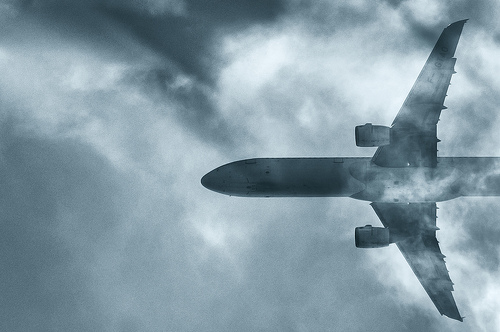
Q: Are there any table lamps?
A: No, there are no table lamps.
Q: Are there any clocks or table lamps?
A: No, there are no table lamps or clocks.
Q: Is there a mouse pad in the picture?
A: No, there are no mouse pads.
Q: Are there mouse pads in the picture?
A: No, there are no mouse pads.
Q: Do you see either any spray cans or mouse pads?
A: No, there are no mouse pads or spray cans.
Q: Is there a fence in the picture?
A: No, there are no fences.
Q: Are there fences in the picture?
A: No, there are no fences.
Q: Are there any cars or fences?
A: No, there are no fences or cars.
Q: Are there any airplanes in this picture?
A: Yes, there is an airplane.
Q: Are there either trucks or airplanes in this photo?
A: Yes, there is an airplane.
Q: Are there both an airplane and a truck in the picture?
A: No, there is an airplane but no trucks.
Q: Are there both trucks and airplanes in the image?
A: No, there is an airplane but no trucks.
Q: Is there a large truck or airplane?
A: Yes, there is a large airplane.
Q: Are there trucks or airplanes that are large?
A: Yes, the airplane is large.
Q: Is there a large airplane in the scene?
A: Yes, there is a large airplane.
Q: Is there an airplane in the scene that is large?
A: Yes, there is an airplane that is large.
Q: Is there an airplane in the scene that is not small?
A: Yes, there is a large airplane.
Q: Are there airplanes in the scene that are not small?
A: Yes, there is a large airplane.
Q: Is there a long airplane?
A: Yes, there is a long airplane.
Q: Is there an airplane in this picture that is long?
A: Yes, there is a long airplane.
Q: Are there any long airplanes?
A: Yes, there is a long airplane.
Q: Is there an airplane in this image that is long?
A: Yes, there is an airplane that is long.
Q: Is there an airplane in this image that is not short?
A: Yes, there is a long airplane.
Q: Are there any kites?
A: No, there are no kites.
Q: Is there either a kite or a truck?
A: No, there are no kites or trucks.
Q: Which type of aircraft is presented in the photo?
A: The aircraft is an airplane.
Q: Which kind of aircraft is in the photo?
A: The aircraft is an airplane.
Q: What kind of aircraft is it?
A: The aircraft is an airplane.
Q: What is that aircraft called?
A: This is an airplane.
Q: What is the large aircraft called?
A: The aircraft is an airplane.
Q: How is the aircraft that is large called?
A: The aircraft is an airplane.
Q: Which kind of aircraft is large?
A: The aircraft is an airplane.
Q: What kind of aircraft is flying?
A: The aircraft is an airplane.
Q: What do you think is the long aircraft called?
A: The aircraft is an airplane.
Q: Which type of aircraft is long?
A: The aircraft is an airplane.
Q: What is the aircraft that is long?
A: The aircraft is an airplane.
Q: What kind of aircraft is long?
A: The aircraft is an airplane.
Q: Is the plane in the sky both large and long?
A: Yes, the plane is large and long.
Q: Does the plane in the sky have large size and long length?
A: Yes, the plane is large and long.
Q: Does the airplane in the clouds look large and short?
A: No, the airplane is large but long.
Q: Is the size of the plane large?
A: Yes, the plane is large.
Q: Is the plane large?
A: Yes, the plane is large.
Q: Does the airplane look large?
A: Yes, the airplane is large.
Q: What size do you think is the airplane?
A: The airplane is large.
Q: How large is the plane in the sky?
A: The plane is large.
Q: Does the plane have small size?
A: No, the plane is large.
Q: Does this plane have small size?
A: No, the plane is large.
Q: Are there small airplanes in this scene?
A: No, there is an airplane but it is large.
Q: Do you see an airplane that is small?
A: No, there is an airplane but it is large.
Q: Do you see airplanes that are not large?
A: No, there is an airplane but it is large.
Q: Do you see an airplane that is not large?
A: No, there is an airplane but it is large.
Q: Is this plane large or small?
A: The plane is large.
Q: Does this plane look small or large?
A: The plane is large.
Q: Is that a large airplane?
A: Yes, that is a large airplane.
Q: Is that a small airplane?
A: No, that is a large airplane.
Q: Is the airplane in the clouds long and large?
A: Yes, the airplane is long and large.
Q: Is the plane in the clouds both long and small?
A: No, the plane is long but large.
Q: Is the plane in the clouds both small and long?
A: No, the plane is long but large.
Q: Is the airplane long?
A: Yes, the airplane is long.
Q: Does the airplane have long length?
A: Yes, the airplane is long.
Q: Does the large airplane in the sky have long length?
A: Yes, the airplane is long.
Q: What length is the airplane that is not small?
A: The airplane is long.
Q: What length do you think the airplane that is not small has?
A: The airplane has long length.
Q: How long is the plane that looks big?
A: The plane is long.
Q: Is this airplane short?
A: No, the airplane is long.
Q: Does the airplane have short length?
A: No, the airplane is long.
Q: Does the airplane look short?
A: No, the airplane is long.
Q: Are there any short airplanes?
A: No, there is an airplane but it is long.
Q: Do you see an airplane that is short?
A: No, there is an airplane but it is long.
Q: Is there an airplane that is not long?
A: No, there is an airplane but it is long.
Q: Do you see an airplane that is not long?
A: No, there is an airplane but it is long.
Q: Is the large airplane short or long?
A: The plane is long.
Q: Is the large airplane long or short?
A: The plane is long.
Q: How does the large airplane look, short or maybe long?
A: The plane is long.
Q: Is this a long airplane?
A: Yes, this is a long airplane.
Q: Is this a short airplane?
A: No, this is a long airplane.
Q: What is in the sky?
A: The airplane is in the sky.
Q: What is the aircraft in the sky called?
A: The aircraft is an airplane.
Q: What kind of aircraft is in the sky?
A: The aircraft is an airplane.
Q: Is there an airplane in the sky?
A: Yes, there is an airplane in the sky.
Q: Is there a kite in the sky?
A: No, there is an airplane in the sky.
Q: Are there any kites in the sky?
A: No, there is an airplane in the sky.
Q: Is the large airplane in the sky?
A: Yes, the plane is in the sky.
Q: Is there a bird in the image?
A: No, there are no birds.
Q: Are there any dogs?
A: No, there are no dogs.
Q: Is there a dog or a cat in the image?
A: No, there are no dogs or cats.